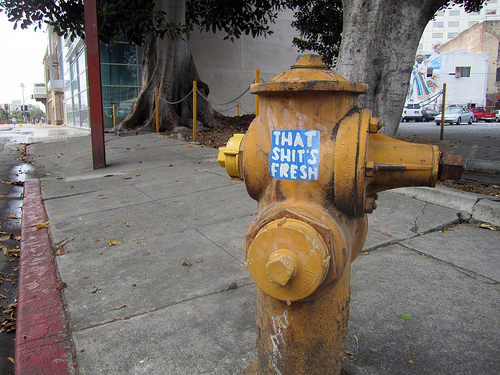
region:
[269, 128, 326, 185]
"That shits fresh" sign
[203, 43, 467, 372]
Yellow and brown fire hydrant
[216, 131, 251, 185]
Bright yellow top of hydrant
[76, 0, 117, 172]
Tall red pole on side walk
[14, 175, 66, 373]
Red edge of side walk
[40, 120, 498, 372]
Grey tiled side walk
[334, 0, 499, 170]
Grey thick tree stem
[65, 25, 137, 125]
Blue glass window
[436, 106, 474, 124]
White car in background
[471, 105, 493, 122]
Red car in the background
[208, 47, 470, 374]
old yellow fire hydrant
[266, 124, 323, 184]
blue sticker with white writing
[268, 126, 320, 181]
sticker on the fire hydrant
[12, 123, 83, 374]
red paint on the curb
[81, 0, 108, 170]
a square red post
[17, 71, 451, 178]
row of yellow posts with chains between them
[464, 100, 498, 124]
red truck in the background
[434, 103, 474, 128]
a gray car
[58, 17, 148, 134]
glass walls on the front of the building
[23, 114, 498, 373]
a sidewalk with leaves on it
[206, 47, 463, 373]
Hydrant on a sidewalk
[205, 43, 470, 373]
Hydrant is on a sidewalk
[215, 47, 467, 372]
Fire hydrant on a sidewalk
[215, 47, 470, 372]
Fire hydrant is on a sidewalk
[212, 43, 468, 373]
Yellow hydrant on a sidewalk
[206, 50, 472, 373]
Yellow hydrant is on a sidewalk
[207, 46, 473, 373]
Yellow fire hydrant on a sidewalk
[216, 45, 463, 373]
Yellow fire hydrant is on a sidewalk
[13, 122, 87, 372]
Curb painted red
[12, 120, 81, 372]
Curb is painted red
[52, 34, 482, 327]
this a fire hydrant in a city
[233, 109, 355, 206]
someone has placed a vulgar sign on the hydrant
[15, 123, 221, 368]
this street is rundown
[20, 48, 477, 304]
this place looks raggedy and old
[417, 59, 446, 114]
some kind of amusement ride in the background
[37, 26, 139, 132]
a building along the street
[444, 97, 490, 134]
cars in the area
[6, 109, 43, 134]
people far away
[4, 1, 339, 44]
trees above the street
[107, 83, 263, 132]
a yellow pole chainlink barrier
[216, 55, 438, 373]
yellow fire hydrant in sidewalk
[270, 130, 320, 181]
blue sticker on hydrant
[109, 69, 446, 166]
metal and chain fence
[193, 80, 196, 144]
yellow pole in ground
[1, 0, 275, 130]
tree with green leaves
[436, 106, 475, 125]
silver car in lot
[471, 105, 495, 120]
red truck in lot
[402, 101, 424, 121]
white van in lot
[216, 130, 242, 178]
yellow cap on hydrant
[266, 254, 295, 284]
yellow bolt on hydrant